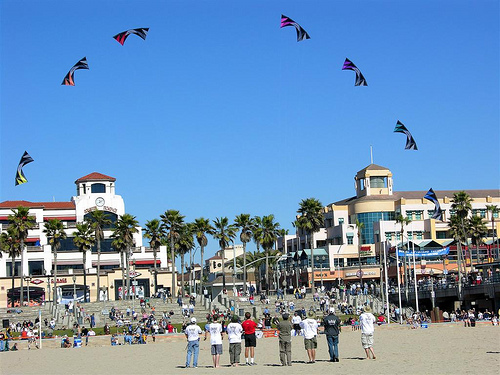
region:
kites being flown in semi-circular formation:
[10, 0, 450, 233]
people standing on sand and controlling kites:
[21, 7, 446, 370]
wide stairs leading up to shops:
[5, 255, 400, 332]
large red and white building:
[5, 170, 175, 300]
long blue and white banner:
[385, 235, 450, 260]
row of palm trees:
[0, 195, 320, 295]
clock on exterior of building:
[75, 170, 125, 215]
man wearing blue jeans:
[176, 330, 202, 370]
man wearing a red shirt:
[235, 307, 258, 338]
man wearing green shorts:
[299, 328, 321, 357]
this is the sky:
[147, 59, 331, 169]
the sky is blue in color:
[153, 80, 260, 154]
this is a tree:
[158, 209, 182, 292]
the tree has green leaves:
[166, 209, 176, 221]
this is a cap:
[188, 315, 196, 322]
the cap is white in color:
[191, 317, 197, 320]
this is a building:
[334, 168, 411, 248]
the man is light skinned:
[251, 350, 253, 354]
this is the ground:
[390, 332, 447, 364]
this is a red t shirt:
[244, 322, 254, 332]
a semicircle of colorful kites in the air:
[0, 3, 443, 225]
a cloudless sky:
[1, 1, 498, 276]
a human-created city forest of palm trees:
[0, 191, 497, 322]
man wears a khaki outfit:
[273, 311, 295, 370]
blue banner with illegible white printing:
[395, 243, 448, 260]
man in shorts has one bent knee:
[358, 339, 378, 364]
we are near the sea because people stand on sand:
[0, 315, 498, 374]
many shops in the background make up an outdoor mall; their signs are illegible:
[1, 186, 498, 323]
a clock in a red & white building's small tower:
[93, 194, 105, 211]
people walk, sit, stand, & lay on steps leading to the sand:
[2, 278, 385, 340]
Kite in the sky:
[42, 53, 130, 123]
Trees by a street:
[40, 201, 325, 313]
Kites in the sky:
[20, 11, 498, 174]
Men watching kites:
[185, 316, 379, 374]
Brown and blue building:
[255, 180, 497, 309]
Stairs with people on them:
[46, 291, 258, 349]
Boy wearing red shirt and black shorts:
[239, 307, 256, 364]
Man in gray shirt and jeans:
[316, 303, 349, 369]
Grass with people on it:
[41, 324, 165, 341]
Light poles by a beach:
[376, 228, 448, 342]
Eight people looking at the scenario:
[174, 305, 384, 370]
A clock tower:
[71, 170, 124, 217]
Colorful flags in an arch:
[10, 10, 455, 215]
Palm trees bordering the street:
[1, 201, 349, 308]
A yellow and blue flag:
[5, 138, 52, 194]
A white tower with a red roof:
[68, 157, 125, 201]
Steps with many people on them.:
[2, 291, 397, 338]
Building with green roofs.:
[271, 243, 331, 282]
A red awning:
[128, 250, 169, 272]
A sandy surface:
[388, 333, 476, 368]